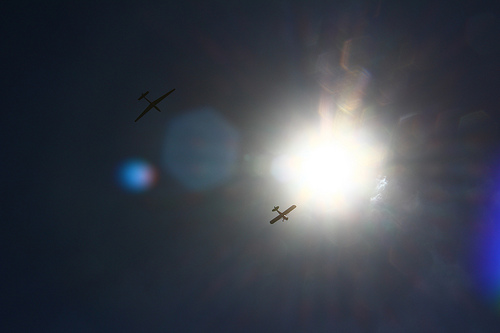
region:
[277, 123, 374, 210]
The sun in the sky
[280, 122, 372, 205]
The sun above the airplanes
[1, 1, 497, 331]
The sky above the airplanes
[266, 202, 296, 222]
An airplane in the sky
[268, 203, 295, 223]
The airplane is flying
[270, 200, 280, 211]
The tail of the airplane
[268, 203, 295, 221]
The wings of the airplane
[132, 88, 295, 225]
Two airplanes in the sky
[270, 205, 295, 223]
The airplane is beneath the sun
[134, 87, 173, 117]
The airplane is following the other airplane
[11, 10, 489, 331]
picture taken outdoors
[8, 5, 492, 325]
picture taken outside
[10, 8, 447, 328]
picture takenduring the day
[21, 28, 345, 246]
two planes in the sky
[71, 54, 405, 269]
the sun is bright in the sky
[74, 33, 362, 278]
a plane and a glider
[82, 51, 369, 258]
the plane is towing the glider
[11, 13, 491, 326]
the sky is void of clouds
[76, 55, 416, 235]
sun spots in the picture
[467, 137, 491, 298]
a bright blue spot on the picture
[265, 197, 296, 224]
plane silhouetted against sky flying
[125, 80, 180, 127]
plane silhouetted against sky flying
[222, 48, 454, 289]
enormous sun spot reflection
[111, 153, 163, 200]
blue rainbow colored light spot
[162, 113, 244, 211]
octagonal light blue light spot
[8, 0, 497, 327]
deep blue cloudless sky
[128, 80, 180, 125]
plane with long wing span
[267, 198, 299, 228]
smaller plane with single engine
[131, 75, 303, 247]
two planes flying in synchronisity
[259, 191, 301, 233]
airplane near the sun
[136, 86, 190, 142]
airplane near the sun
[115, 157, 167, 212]
orb near the sun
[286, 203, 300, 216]
wing of the plane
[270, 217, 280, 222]
wing of the plane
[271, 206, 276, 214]
tail of the plane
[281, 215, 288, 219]
nose of the plane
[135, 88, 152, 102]
tail of the plane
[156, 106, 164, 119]
nose of the plane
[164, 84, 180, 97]
wing of the plane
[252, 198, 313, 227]
A small black plane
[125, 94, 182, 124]
A small black plane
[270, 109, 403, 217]
A bright sun rays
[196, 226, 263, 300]
A bright sun rays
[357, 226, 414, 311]
A bright sun rays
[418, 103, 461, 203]
A bright sun rays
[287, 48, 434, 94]
A bright sun rays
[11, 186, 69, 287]
A blue sky lining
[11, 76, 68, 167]
A blue sky lining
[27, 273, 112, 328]
A blue sky lining